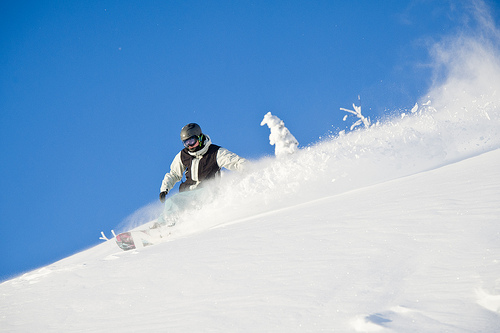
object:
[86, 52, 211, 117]
clouds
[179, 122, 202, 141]
cap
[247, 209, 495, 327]
snow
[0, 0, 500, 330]
sky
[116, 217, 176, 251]
snowboard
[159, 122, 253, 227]
person